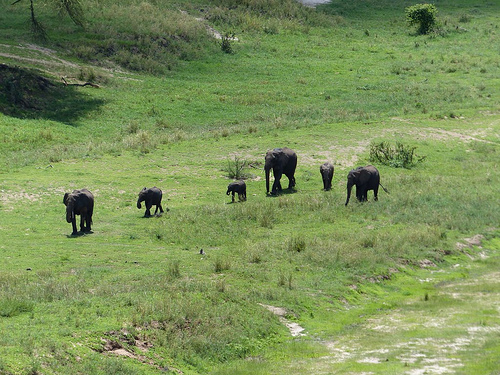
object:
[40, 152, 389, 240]
elephant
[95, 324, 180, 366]
eroded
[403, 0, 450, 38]
bush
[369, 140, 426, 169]
shrub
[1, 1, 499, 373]
grass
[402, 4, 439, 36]
tree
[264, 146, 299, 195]
elephant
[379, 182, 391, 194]
tail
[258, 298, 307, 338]
barren patch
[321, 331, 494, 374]
barren patch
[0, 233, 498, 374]
grass.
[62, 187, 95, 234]
elephant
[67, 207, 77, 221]
tusks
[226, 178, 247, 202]
elephant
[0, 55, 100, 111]
tree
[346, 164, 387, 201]
elephant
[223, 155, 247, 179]
bush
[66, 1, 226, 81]
branch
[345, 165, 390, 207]
elephant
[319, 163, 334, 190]
elephant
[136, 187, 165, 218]
elephant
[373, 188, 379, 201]
leg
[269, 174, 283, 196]
leg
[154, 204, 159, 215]
leg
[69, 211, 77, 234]
leg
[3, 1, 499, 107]
background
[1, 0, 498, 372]
ground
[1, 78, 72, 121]
shadow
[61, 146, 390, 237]
elephants